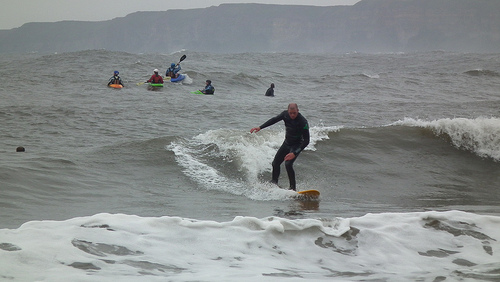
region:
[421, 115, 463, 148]
part of a water splash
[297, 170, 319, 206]
edge of a swimming board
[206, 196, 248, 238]
part of a water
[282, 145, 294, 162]
part of a hand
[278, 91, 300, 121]
face of a man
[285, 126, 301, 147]
chest of a man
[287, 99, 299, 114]
head of a man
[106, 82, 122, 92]
part of a swimming board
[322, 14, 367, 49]
part of a hill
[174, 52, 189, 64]
part of a paddle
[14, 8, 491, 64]
A large cliff overlooking the ocean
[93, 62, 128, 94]
Kayaker with an orange kayak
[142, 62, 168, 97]
Kayaker with a green kayak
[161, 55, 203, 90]
Kayaker with a blue kayak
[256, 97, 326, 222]
Surfer in a black wetsuit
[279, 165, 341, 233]
An orange surfboard in the ocean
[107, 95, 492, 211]
A wave breaks towards the shore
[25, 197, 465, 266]
The surf is frothy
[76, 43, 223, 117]
A group of four people kayak in the ocean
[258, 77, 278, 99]
A man swims in waist deep water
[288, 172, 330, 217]
Yellow surfboard is sticking out of water.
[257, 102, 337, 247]
Man is wearing dark wet suit.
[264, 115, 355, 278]
Man is standing on surfboard.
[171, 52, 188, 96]
Person is in kayak.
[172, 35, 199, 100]
Man is holding a paddle.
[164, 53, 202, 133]
Man is in a blue kayak.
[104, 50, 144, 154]
Person is in an orange kayak.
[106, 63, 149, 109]
Person is wearing a blue helmet.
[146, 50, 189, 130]
Person is sitting in green kayak.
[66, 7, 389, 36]
Mountains in the background.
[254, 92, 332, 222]
man wearing black swimwear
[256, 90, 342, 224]
man surfing on the water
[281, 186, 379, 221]
yellow surf board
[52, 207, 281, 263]
bubbles in the ocean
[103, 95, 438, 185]
waves on the ocean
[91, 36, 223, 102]
four people kayaking on the ocean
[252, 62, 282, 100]
man waling on the water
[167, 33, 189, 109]
man paddling on the waves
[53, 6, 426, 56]
mountain at the end of ocean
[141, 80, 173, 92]
green kayaking boat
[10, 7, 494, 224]
people surfing in gray ocean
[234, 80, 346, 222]
white man wearing black body suit standing upright on board in water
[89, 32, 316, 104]
five people on boards with paddles in water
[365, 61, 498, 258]
crashing wave in ocean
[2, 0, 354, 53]
background mountain landscape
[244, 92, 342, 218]
man in black riding a crashing wave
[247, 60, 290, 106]
person in distance swimming in water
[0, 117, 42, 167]
object floating in water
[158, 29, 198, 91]
person on blue board with paddle navigating water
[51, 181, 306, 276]
sea foam from ocean waves